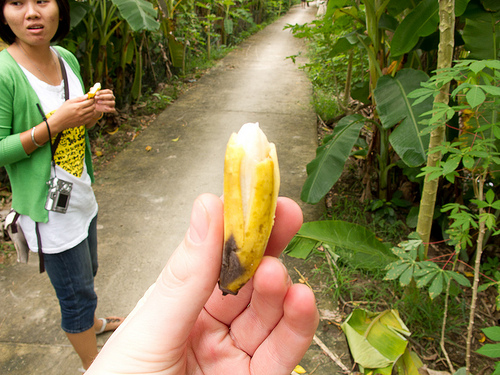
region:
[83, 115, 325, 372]
Hand holding a banana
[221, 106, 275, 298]
A small banana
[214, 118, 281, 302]
A ripened small banana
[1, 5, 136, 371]
Woman in a green cardigan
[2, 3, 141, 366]
Woman in a white shirt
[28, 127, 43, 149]
A silver bracelet on wrist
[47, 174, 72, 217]
A silver digital camera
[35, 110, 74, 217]
A digital camera hanging on wrist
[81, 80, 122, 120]
Woman holding a banana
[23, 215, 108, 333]
Women's blue capri jeans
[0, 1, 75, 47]
short black hair on a woman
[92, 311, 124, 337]
a white sandle on a woman's foot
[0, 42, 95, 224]
a green sweater on a woman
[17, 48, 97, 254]
a white shirt with a yellow heart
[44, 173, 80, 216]
a camera hanging off a woman's wrist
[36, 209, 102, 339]
blue jean pants on a woman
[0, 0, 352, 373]
a path through a banana grove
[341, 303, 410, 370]
a yellowed banana leaf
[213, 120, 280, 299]
a tiny banana in a person's hand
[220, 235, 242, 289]
a dark bruise on a banana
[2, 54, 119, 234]
the cardigan is green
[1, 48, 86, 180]
the cardigan is green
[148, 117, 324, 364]
person is holding a banana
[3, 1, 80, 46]
head of a person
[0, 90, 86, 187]
arm of a person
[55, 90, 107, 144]
hand of a person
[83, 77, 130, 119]
hand of a person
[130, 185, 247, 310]
thumb of a person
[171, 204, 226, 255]
nail of a person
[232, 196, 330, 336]
finger of a person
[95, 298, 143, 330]
feet of a person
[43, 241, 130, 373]
leg of a person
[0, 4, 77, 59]
head of a person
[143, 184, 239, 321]
thumb of a person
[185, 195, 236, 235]
nail of a person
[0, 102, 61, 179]
arm of a person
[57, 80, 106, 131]
hand of a person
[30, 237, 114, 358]
leg of a person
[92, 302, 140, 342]
feet of a person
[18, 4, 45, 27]
nose of a person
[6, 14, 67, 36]
mouth of a person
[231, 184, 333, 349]
fingers of a person